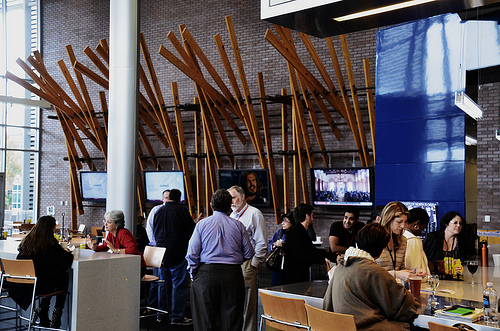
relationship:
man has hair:
[184, 190, 256, 330] [207, 189, 231, 215]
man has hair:
[152, 188, 196, 326] [169, 190, 182, 204]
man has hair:
[226, 186, 268, 330] [226, 185, 246, 199]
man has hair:
[283, 203, 337, 285] [293, 202, 314, 224]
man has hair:
[329, 208, 366, 254] [344, 207, 360, 222]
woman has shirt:
[19, 238, 74, 294] [17, 242, 73, 292]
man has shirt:
[152, 188, 196, 326] [153, 202, 194, 268]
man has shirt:
[283, 203, 337, 285] [279, 222, 336, 283]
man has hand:
[184, 190, 256, 330] [189, 269, 202, 281]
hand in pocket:
[189, 269, 202, 281] [188, 274, 200, 300]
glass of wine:
[468, 261, 479, 289] [467, 260, 478, 287]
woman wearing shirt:
[85, 210, 147, 278] [95, 230, 145, 268]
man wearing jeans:
[152, 188, 196, 326] [156, 262, 187, 318]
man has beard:
[283, 203, 337, 285] [308, 215, 314, 228]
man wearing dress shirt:
[226, 186, 268, 330] [228, 204, 268, 268]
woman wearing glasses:
[85, 210, 147, 278] [102, 218, 114, 224]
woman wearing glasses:
[422, 212, 466, 264] [448, 220, 463, 224]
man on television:
[240, 170, 260, 199] [215, 170, 272, 211]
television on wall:
[215, 170, 272, 211] [39, 0, 376, 253]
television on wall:
[80, 170, 109, 200] [39, 0, 376, 253]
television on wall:
[144, 171, 189, 207] [39, 0, 376, 253]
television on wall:
[309, 166, 374, 211] [39, 0, 376, 253]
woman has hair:
[19, 238, 74, 294] [16, 216, 59, 262]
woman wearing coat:
[319, 221, 422, 329] [322, 256, 420, 330]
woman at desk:
[319, 221, 422, 329] [259, 258, 499, 329]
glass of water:
[426, 276, 439, 307] [427, 275, 438, 289]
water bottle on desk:
[483, 281, 497, 324] [259, 258, 499, 329]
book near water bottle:
[432, 305, 484, 324] [483, 281, 497, 324]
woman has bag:
[266, 210, 294, 284] [266, 246, 282, 270]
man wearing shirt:
[152, 188, 196, 326] [153, 202, 194, 268]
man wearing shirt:
[283, 203, 337, 285] [279, 222, 336, 283]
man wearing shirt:
[329, 208, 366, 254] [328, 222, 367, 261]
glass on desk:
[409, 275, 421, 299] [259, 258, 499, 329]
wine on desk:
[467, 260, 478, 287] [259, 258, 499, 329]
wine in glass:
[467, 260, 478, 287] [468, 261, 479, 289]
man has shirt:
[184, 190, 256, 330] [183, 212, 255, 265]